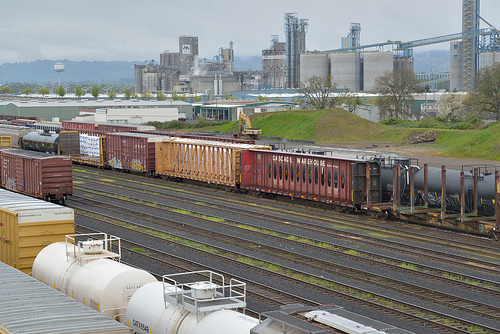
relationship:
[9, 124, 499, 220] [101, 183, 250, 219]
train by tracks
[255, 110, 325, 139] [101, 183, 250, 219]
grass between tracks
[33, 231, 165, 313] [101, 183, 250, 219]
tank on tracks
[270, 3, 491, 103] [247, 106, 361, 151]
refinery behind hill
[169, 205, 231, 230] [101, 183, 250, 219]
grass between tracks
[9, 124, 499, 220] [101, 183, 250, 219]
train on tracks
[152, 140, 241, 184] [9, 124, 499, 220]
car on train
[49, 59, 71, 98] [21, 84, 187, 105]
tower and trees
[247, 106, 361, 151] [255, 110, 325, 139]
hill with grass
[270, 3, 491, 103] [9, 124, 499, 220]
refinery and train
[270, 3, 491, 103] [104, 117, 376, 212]
refinery and cars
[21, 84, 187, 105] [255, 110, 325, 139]
trees next to grass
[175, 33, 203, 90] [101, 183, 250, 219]
building next to tracks